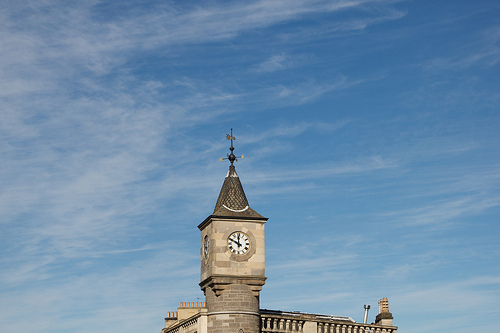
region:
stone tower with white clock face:
[197, 121, 281, 326]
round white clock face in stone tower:
[227, 230, 254, 258]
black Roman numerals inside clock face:
[227, 228, 254, 252]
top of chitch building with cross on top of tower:
[160, 115, 402, 331]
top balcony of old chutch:
[161, 295, 404, 330]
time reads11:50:
[227, 229, 254, 260]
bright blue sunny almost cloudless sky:
[4, 7, 495, 326]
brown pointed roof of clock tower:
[199, 166, 271, 226]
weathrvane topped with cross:
[217, 125, 247, 172]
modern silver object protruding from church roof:
[362, 298, 378, 323]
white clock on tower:
[226, 236, 256, 258]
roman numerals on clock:
[228, 228, 251, 258]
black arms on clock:
[228, 234, 243, 251]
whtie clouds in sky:
[48, 191, 147, 262]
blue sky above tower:
[59, 4, 454, 193]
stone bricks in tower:
[223, 301, 257, 328]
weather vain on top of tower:
[221, 124, 242, 165]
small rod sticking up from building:
[362, 294, 374, 329]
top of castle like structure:
[148, 181, 405, 330]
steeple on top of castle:
[210, 173, 254, 213]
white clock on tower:
[212, 209, 279, 306]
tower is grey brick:
[192, 209, 275, 303]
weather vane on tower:
[212, 114, 254, 191]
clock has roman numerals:
[226, 225, 251, 260]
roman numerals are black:
[231, 225, 248, 254]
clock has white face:
[231, 227, 243, 253]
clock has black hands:
[220, 229, 238, 251]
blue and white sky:
[327, 7, 454, 183]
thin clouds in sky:
[20, 27, 173, 211]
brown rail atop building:
[238, 312, 393, 329]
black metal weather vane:
[217, 127, 246, 172]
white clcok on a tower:
[221, 227, 257, 263]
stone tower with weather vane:
[195, 120, 273, 332]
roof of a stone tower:
[197, 161, 270, 230]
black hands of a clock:
[227, 229, 244, 249]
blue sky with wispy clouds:
[3, 4, 497, 331]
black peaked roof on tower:
[193, 163, 270, 227]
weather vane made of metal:
[215, 124, 245, 171]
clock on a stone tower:
[200, 232, 210, 264]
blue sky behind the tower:
[0, 2, 498, 332]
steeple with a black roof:
[197, 128, 269, 331]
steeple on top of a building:
[157, 126, 398, 331]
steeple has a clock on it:
[227, 231, 251, 256]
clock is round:
[226, 231, 251, 255]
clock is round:
[201, 234, 210, 263]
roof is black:
[196, 164, 269, 231]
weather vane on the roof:
[217, 126, 244, 167]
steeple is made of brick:
[195, 127, 269, 331]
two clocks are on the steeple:
[227, 232, 252, 255]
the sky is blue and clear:
[0, 1, 496, 331]